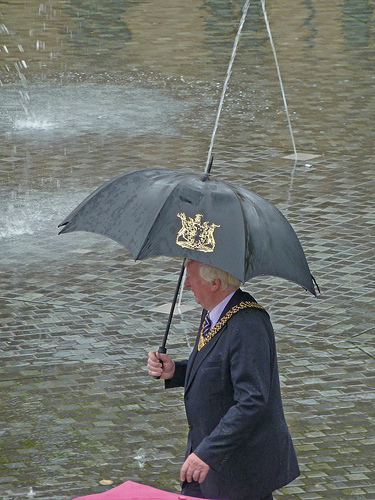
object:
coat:
[153, 289, 298, 495]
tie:
[203, 315, 210, 339]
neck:
[200, 291, 238, 313]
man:
[145, 239, 298, 497]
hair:
[183, 255, 241, 289]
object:
[72, 479, 205, 498]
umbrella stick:
[158, 257, 185, 345]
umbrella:
[57, 169, 319, 377]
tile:
[282, 147, 321, 164]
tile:
[318, 383, 342, 402]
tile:
[299, 204, 324, 217]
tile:
[147, 301, 195, 316]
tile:
[79, 334, 97, 347]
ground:
[4, 7, 367, 492]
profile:
[183, 259, 212, 308]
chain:
[197, 299, 266, 354]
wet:
[30, 35, 190, 140]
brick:
[4, 238, 33, 259]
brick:
[12, 430, 93, 493]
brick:
[308, 351, 372, 481]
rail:
[2, 18, 44, 116]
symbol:
[175, 211, 220, 252]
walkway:
[1, 3, 373, 498]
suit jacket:
[162, 289, 300, 498]